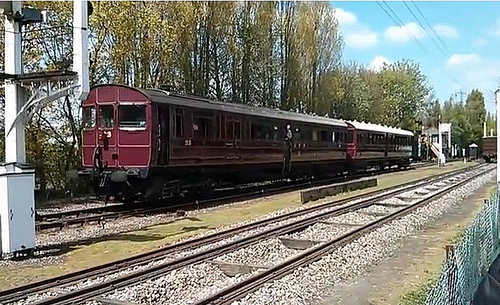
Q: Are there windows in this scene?
A: Yes, there is a window.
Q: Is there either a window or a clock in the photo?
A: Yes, there is a window.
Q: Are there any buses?
A: No, there are no buses.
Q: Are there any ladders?
A: No, there are no ladders.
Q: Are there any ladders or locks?
A: No, there are no ladders or locks.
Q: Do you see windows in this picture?
A: Yes, there is a window.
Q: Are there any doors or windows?
A: Yes, there is a window.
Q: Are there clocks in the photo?
A: No, there are no clocks.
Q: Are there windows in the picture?
A: Yes, there is a window.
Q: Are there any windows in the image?
A: Yes, there is a window.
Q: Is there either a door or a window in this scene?
A: Yes, there is a window.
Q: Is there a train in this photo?
A: Yes, there is a train.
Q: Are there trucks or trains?
A: Yes, there is a train.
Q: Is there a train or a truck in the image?
A: Yes, there is a train.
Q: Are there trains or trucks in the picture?
A: Yes, there is a train.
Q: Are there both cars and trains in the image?
A: Yes, there are both a train and cars.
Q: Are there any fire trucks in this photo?
A: No, there are no fire trucks.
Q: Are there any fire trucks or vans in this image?
A: No, there are no fire trucks or vans.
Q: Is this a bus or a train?
A: This is a train.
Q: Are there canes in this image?
A: No, there are no canes.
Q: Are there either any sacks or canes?
A: No, there are no canes or sacks.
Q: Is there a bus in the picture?
A: No, there are no buses.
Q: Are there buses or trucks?
A: No, there are no buses or trucks.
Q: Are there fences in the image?
A: Yes, there is a fence.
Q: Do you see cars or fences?
A: Yes, there is a fence.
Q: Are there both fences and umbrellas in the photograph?
A: No, there is a fence but no umbrellas.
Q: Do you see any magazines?
A: No, there are no magazines.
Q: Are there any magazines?
A: No, there are no magazines.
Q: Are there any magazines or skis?
A: No, there are no magazines or skis.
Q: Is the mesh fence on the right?
A: Yes, the fence is on the right of the image.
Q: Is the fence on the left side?
A: No, the fence is on the right of the image.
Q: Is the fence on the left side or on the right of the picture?
A: The fence is on the right of the image.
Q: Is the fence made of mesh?
A: Yes, the fence is made of mesh.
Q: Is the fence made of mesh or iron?
A: The fence is made of mesh.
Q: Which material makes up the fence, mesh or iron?
A: The fence is made of mesh.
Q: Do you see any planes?
A: No, there are no planes.